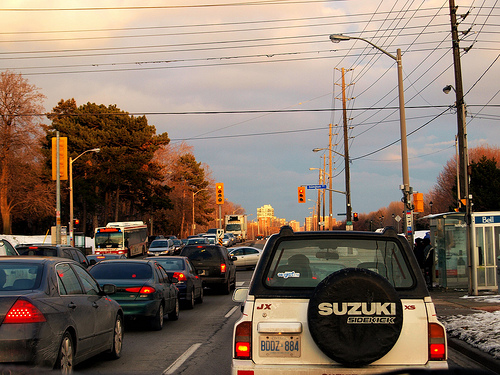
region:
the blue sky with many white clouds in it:
[1, 2, 499, 202]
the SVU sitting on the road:
[231, 231, 444, 373]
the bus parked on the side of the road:
[89, 217, 151, 260]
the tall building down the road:
[255, 203, 273, 232]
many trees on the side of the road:
[3, 73, 242, 229]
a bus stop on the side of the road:
[412, 208, 467, 286]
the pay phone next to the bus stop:
[473, 212, 498, 291]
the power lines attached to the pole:
[0, 6, 495, 140]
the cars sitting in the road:
[2, 225, 234, 372]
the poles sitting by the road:
[304, 23, 472, 213]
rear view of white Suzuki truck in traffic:
[230, 220, 454, 368]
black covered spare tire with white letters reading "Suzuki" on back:
[305, 263, 403, 369]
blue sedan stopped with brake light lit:
[1, 243, 136, 365]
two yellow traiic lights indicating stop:
[207, 175, 312, 209]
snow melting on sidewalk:
[445, 290, 498, 360]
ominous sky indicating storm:
[11, 0, 497, 213]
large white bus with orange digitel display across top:
[90, 219, 152, 259]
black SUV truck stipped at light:
[180, 238, 237, 295]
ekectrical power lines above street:
[5, 0, 499, 221]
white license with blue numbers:
[255, 330, 309, 360]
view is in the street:
[38, 121, 373, 373]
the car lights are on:
[119, 268, 194, 311]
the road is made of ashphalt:
[181, 322, 208, 373]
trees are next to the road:
[48, 98, 252, 258]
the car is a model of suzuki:
[263, 219, 433, 371]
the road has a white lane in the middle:
[164, 301, 237, 370]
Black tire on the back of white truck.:
[302, 299, 334, 370]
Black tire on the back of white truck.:
[312, 278, 424, 326]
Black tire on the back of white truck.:
[228, 284, 235, 369]